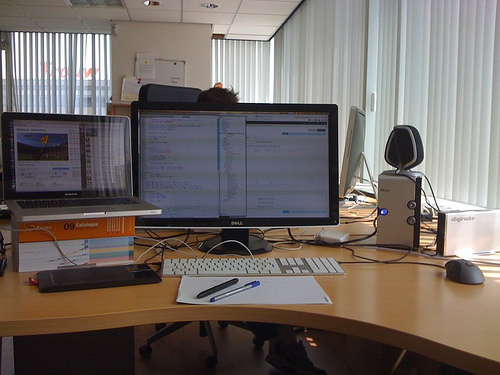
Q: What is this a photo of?
A: Office desk and computer equipment.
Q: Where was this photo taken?
A: In an office.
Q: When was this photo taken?
A: During the daytime.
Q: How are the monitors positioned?
A: On the top of the desk.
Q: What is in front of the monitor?
A: A keyboard, paper and ink pens.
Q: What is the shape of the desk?
A: It has a curved edge.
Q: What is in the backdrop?
A: Windows.